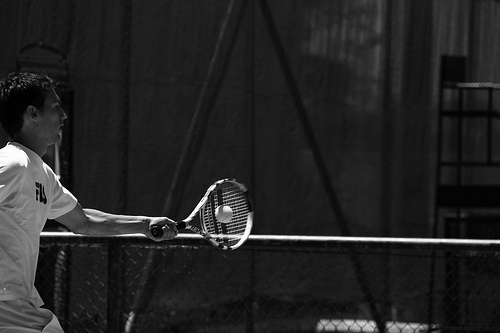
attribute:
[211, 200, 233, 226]
ball — tennis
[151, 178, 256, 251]
racket — tennis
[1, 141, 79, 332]
shirt — white, printed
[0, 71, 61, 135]
hair — short, dark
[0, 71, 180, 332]
man — playing, young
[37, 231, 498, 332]
net — black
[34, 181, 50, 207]
logo — black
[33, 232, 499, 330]
fence — chain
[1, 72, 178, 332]
player — young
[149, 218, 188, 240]
handle — black